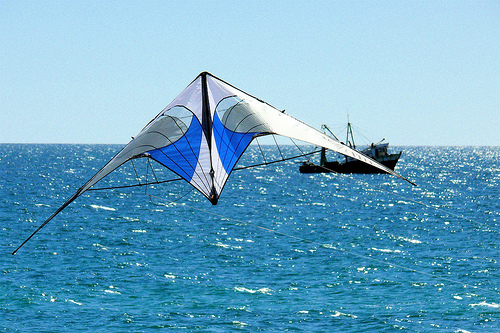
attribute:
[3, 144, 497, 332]
ocean — calm, blue, brilliant, sparkling, tranquil, choppy, soothing, large, landscape, shiny, effects, sea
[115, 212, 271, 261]
ripples — small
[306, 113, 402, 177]
ship — sailing, black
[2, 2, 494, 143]
sky — bluey, cloudless, clear, free, light blue, blue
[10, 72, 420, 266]
kite — blue, white, big, large, gray, flying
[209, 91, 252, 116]
section — blue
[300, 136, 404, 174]
boat — passing by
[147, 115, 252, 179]
triangles — blue